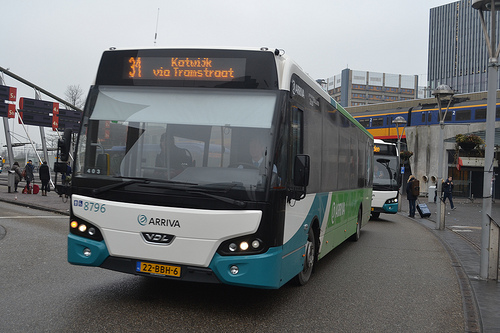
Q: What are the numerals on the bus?
A: 8796.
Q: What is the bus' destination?
A: Kotwijk via Tramstroat.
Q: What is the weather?
A: Overcast and gray.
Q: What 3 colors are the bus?
A: White, blue, and green.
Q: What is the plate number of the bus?
A: 22BBH6.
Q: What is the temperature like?
A: Cold.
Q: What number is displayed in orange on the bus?
A: 31.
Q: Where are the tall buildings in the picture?
A: Right.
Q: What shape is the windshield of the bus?
A: Rectangle.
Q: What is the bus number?
A: 8796.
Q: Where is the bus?
A: On the street.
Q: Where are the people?
A: Next to the bus.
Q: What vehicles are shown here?
A: Buses.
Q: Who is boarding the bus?
A: A passenger in brown.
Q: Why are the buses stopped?
A: To allow people on and off the bus.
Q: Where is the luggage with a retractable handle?
A: Behind the passenger, who is beside the more distant bus.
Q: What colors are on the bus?
A: Blue, green, white and black.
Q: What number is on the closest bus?
A: 31.